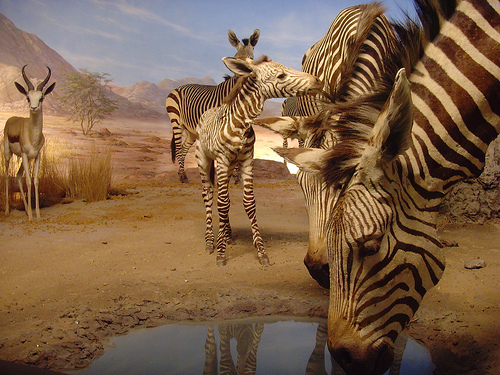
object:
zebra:
[161, 25, 284, 182]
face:
[265, 58, 327, 99]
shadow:
[189, 291, 260, 374]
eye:
[276, 71, 291, 84]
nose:
[310, 74, 322, 86]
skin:
[204, 118, 248, 150]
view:
[60, 15, 184, 111]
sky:
[98, 23, 155, 66]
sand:
[118, 220, 142, 240]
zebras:
[191, 44, 326, 271]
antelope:
[0, 58, 60, 224]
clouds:
[99, 15, 224, 68]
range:
[62, 67, 174, 114]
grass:
[68, 167, 76, 196]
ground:
[85, 194, 187, 278]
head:
[311, 56, 448, 373]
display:
[0, 21, 499, 363]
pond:
[68, 292, 474, 374]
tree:
[58, 64, 122, 134]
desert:
[79, 127, 161, 183]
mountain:
[0, 10, 162, 121]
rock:
[463, 247, 488, 275]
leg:
[237, 158, 274, 268]